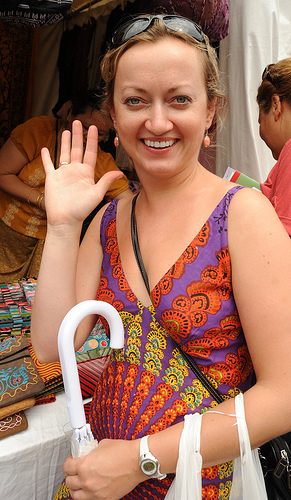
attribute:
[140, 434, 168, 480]
wristwatch — white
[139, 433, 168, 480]
watch — white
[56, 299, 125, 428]
handle — white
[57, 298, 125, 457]
umbrella — white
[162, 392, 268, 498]
plastic bag — white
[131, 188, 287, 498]
purse — black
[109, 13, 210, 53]
sunglasses — black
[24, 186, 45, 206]
ring bracelet — gold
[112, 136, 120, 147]
earring — red, silver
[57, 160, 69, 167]
wedding ring — Silver colored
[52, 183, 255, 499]
dress — purple, red, yellow, blue, black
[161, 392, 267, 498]
shopping bag — white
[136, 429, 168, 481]
wristwatch — white